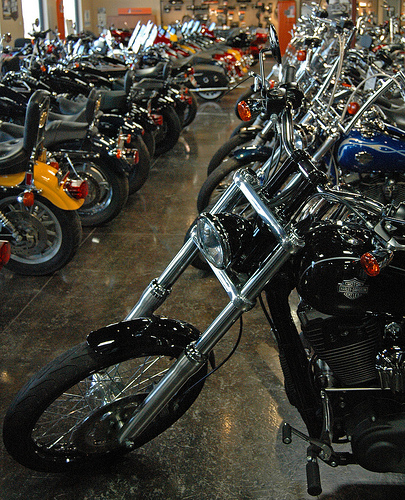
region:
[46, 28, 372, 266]
A lot of motorcycles in the shop.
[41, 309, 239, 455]
The tire is black.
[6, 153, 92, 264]
The back part of the bike is yellow.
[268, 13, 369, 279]
Motorcycles parked in a row.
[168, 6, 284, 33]
Items on sale on the back wall.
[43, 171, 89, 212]
The back lights on the motorcycle.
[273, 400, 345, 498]
The kick stick is on the motorcycle.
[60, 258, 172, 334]
The floor has big tiles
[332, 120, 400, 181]
The motorcycle is blue.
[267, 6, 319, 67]
the door is orange.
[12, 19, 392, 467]
several motorcycles lined up in a store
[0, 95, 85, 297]
back of a yellow motorcycle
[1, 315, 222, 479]
black motorcycle wheel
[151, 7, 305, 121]
mirror reflecting motorcycles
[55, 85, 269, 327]
narrow isle between motorcycles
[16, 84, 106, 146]
motorcycle seat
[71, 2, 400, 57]
back wall of a motorcycle store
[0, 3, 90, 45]
windows with bright light shining through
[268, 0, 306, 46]
orange wall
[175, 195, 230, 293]
motorcycle headlights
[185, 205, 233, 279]
the headlight of a bike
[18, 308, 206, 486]
a black tire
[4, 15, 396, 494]
a showroom for motorcycles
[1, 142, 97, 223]
a yellow bike tail with red lights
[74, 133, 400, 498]
a black bike parked in a showroom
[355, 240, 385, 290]
a small orange light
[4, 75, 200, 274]
six tires in a row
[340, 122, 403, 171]
a blue and silver bike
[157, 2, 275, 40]
tools hanging on a wall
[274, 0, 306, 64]
an orange door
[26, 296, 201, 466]
A front tire of a motorcycle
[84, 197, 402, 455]
A black motorcycle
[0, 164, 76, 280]
A yellow motorcycle tire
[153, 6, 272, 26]
Parts for bikes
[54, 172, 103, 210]
The rear light of a motorcycle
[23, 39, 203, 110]
A group of harleys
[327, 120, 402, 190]
A blue motorcycle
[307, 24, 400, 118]
Chrome motorcycle handles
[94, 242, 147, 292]
Grease tile of the store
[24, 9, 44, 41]
A window to the store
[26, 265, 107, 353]
the floor is black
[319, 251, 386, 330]
the emblem says harley davidson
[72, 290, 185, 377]
the bike is black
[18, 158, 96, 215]
the bike is yellow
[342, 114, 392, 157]
the bike is blue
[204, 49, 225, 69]
the bike is red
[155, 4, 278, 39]
bike parts in the background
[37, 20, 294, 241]
a lot of bikes in the background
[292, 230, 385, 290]
the black bike has a grey stripe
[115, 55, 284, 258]
the bike are parked outside